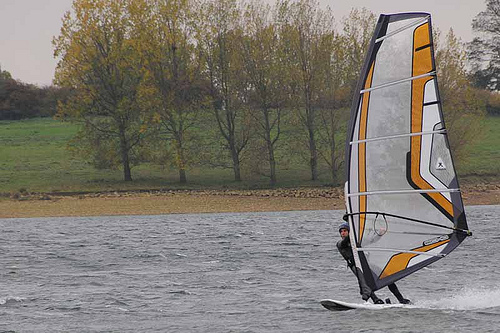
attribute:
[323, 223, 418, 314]
man — wearing helmet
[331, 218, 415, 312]
man — on surfboard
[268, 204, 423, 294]
person — near land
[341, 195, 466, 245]
cord — with parasail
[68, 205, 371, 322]
water — with parasail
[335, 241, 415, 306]
swim suit — dark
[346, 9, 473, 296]
sail — near land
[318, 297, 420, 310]
surfboard — on bed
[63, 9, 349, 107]
leaves — yellow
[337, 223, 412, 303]
man — with parasail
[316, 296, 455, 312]
board — near land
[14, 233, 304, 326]
water — near land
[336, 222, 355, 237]
hat — near land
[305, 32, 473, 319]
sail — near land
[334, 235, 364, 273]
jacket — near land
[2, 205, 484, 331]
water — near land